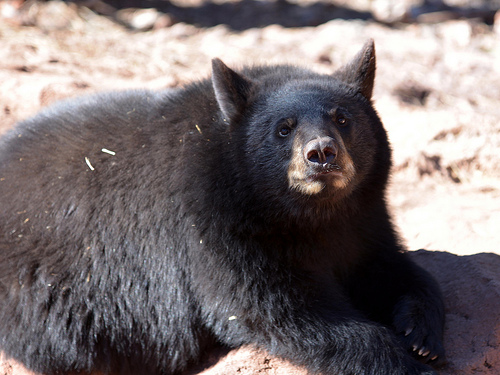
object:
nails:
[402, 328, 438, 361]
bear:
[0, 38, 445, 375]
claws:
[405, 327, 440, 360]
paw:
[363, 318, 442, 375]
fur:
[87, 218, 194, 370]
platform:
[1, 248, 499, 372]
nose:
[303, 122, 340, 171]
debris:
[82, 146, 117, 173]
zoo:
[0, 0, 500, 375]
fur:
[23, 137, 165, 220]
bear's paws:
[321, 301, 447, 375]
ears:
[210, 38, 376, 124]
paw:
[343, 326, 425, 375]